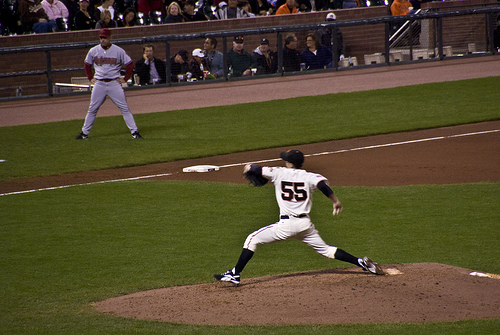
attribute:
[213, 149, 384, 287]
pitcher — throwing, pitching, thowing, major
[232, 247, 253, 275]
sock — black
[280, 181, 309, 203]
jersey — numbered, number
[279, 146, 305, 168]
hat — black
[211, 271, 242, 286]
cleat — black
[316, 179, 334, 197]
sleeve — black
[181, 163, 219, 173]
base — white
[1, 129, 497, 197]
line — white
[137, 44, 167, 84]
spectator — watching, watchig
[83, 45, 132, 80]
shirt — grey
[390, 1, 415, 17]
top — orange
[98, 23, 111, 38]
cap — red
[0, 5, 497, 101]
fence — black